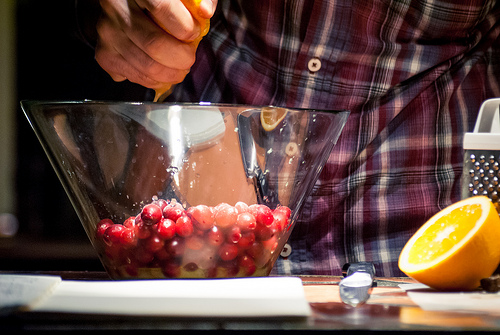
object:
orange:
[152, 0, 209, 103]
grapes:
[96, 198, 291, 278]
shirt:
[169, 0, 500, 274]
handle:
[463, 97, 500, 151]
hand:
[96, 0, 217, 90]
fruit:
[146, 0, 213, 105]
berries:
[97, 199, 293, 278]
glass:
[21, 99, 352, 282]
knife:
[339, 262, 376, 308]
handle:
[342, 261, 377, 279]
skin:
[397, 195, 491, 274]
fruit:
[398, 195, 499, 290]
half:
[397, 195, 498, 291]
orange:
[397, 195, 498, 294]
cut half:
[151, 0, 210, 103]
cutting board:
[0, 269, 500, 335]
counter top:
[0, 267, 497, 335]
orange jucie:
[153, 10, 212, 101]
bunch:
[96, 198, 292, 279]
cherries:
[97, 199, 291, 280]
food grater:
[459, 96, 499, 215]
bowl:
[16, 99, 351, 281]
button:
[308, 58, 323, 72]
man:
[92, 0, 500, 275]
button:
[279, 243, 292, 257]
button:
[285, 142, 299, 158]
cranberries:
[97, 199, 292, 279]